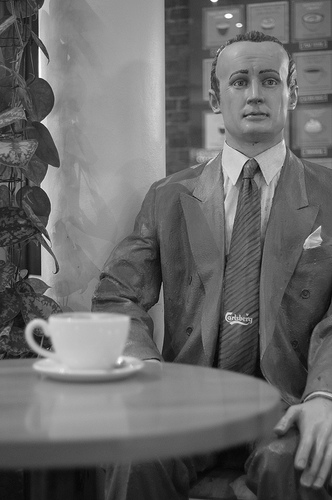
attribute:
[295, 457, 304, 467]
fingernail — white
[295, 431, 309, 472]
finger — plastic, white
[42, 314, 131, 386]
cup — white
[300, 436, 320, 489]
finger — white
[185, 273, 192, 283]
button — plastic, black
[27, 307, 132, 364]
cup — small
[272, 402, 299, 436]
finger — white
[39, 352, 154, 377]
plate — small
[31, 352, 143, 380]
plate — small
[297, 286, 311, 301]
button — black, plastic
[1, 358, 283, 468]
table — circular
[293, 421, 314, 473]
finger — white, plastic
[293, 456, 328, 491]
plastic fingernail — white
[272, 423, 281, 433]
fingernail — white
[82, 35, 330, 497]
statue — plastic